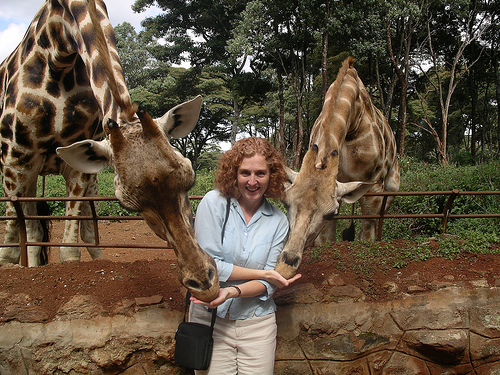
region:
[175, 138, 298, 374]
woman with red hair feeding giraffes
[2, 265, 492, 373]
stone wall behind woman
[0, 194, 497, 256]
rust colored fence above stone wall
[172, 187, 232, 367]
black purse hanging from woman's shoulder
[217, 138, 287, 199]
woman's curly red hair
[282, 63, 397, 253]
the giraffe on the right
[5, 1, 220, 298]
the giraffe on the left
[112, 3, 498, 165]
tall trees behind the giraffes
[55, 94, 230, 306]
left giraffe eating out of woman's hand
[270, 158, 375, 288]
right giraffe eating out of woman's hand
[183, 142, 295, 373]
woman feeding two giraffes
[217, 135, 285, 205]
woman is smiling happily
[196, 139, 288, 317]
woman wearing light blue shirt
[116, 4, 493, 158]
tall trees in background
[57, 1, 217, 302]
giraffe with head bent over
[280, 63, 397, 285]
giraffe with head bent over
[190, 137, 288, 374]
woman wearing tan pants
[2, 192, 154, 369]
metal fence on concrete and dirt wall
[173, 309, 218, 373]
woman carrying a black bag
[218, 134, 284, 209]
woman with dark blonde curly hair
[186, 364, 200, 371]
White apple mouse on the desk.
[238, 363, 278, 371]
White apple mouse on the desk.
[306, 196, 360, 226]
White apple mouse on the desk.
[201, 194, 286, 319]
the shirt is blue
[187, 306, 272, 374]
the pants are tan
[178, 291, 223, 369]
the bag is black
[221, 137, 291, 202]
the hair is brown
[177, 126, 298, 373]
the woman is feeding the giraffe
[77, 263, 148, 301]
the soil is brown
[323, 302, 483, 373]
the rocks are brown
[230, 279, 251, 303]
bracelet is on the hand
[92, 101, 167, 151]
the horns are short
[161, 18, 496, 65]
trees are in the background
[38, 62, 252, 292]
head of a giraffe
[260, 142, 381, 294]
head of a giraffe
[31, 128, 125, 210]
ear of a giraffe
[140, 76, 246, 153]
ear of a giraffe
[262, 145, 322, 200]
ear of a giraffe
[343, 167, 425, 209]
ear of a giraffe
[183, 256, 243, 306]
mouth of a giraffe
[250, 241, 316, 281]
mouth of a giraffe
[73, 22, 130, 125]
neck of a giraffe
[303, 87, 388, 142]
neck of a giraffe